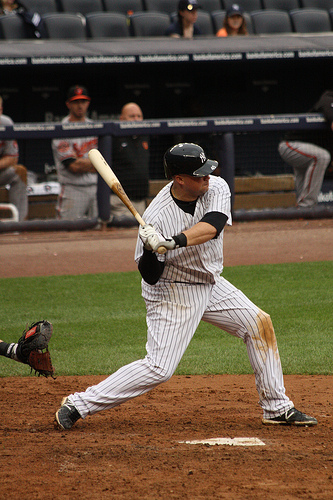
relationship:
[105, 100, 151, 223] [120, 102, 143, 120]
man has a head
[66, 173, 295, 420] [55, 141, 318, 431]
uniform on man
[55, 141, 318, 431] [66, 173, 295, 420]
man wearing a uniform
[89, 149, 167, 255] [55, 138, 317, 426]
baseball bat in hand of man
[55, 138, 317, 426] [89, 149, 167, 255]
man with a baseball bat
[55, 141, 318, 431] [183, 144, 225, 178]
man with a helmet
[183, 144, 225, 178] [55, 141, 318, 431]
helmet on a man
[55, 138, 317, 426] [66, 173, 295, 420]
man wearing uniform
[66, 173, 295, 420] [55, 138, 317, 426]
uniform on man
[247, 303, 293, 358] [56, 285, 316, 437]
dirt on pants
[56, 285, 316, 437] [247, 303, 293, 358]
pants with dirt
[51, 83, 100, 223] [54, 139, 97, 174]
man with arms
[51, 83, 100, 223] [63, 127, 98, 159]
man with chest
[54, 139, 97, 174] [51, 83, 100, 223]
arms on man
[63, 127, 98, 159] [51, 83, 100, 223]
chest on man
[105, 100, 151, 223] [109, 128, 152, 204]
man with a shirt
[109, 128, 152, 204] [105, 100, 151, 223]
shirt on a man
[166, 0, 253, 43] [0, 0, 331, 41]
spectators in bleachers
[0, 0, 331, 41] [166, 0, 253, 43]
bleachers with spectators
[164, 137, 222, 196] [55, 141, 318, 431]
head on man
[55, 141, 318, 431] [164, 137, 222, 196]
man with head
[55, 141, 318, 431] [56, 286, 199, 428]
man with leg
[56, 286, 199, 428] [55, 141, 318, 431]
leg of a man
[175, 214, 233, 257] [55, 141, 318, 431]
arm of a man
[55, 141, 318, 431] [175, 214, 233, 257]
man with an arm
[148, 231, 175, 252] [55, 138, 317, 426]
glove on man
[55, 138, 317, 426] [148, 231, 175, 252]
man with a glove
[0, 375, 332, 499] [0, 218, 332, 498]
dirt on field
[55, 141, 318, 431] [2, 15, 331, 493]
man playing game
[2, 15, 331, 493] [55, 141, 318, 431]
game with man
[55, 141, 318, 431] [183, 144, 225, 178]
man with helmet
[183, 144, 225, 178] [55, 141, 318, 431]
helmet on man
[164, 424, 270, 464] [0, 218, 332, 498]
home plate on field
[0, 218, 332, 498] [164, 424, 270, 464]
field under home plate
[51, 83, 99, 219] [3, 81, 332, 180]
man in dugout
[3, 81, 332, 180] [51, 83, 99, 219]
dugout with man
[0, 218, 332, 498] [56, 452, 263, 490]
field with dirt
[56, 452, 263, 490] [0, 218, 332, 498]
dirt with field